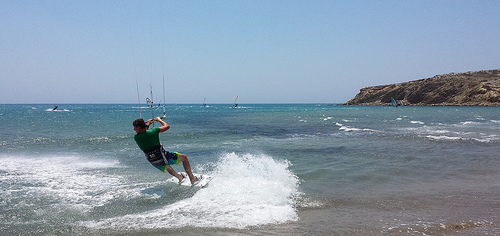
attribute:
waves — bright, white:
[4, 137, 299, 227]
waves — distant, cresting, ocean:
[277, 111, 496, 138]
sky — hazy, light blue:
[3, 0, 499, 101]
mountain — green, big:
[343, 72, 489, 101]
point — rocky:
[344, 68, 499, 103]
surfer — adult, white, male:
[116, 81, 216, 193]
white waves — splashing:
[1, 142, 303, 234]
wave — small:
[82, 145, 306, 231]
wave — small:
[2, 147, 160, 215]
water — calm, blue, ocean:
[183, 98, 429, 173]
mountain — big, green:
[47, 94, 68, 116]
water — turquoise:
[209, 90, 420, 152]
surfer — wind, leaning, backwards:
[37, 98, 326, 218]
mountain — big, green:
[337, 67, 488, 107]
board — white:
[159, 169, 218, 191]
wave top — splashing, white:
[203, 150, 305, 232]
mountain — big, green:
[347, 67, 498, 111]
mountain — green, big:
[335, 54, 497, 110]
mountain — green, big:
[337, 58, 497, 106]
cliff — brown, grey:
[341, 61, 498, 111]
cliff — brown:
[348, 64, 499, 106]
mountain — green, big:
[342, 67, 498, 104]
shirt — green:
[135, 126, 166, 160]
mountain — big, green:
[367, 71, 499, 103]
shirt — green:
[130, 124, 169, 163]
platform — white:
[167, 166, 212, 191]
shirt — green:
[135, 128, 160, 151]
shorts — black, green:
[126, 129, 190, 174]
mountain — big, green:
[340, 68, 499, 107]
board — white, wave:
[166, 168, 215, 188]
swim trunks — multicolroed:
[145, 149, 178, 168]